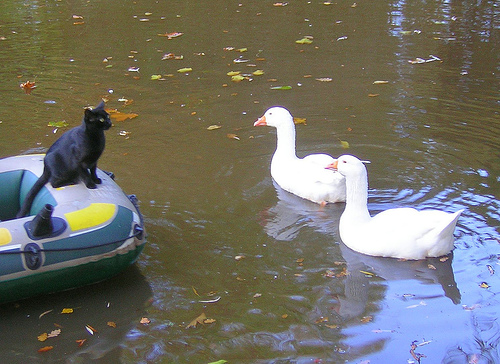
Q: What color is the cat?
A: Black.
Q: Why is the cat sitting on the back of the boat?
A: To look at the swans.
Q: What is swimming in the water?
A: Swans.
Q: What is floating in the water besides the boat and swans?
A: Leaves.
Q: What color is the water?
A: Olive green.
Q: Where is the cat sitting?
A: On the back of the boat.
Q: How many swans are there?
A: Two.